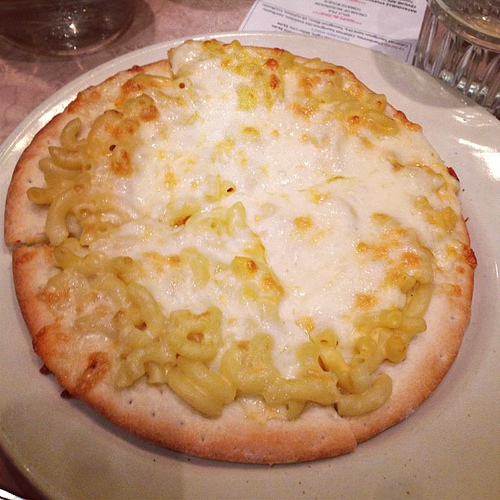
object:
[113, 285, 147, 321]
macaroni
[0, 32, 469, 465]
piece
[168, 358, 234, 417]
macaroni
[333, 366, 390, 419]
macaroni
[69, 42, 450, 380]
cheese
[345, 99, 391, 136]
macaroni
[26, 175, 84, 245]
macaroni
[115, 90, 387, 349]
melted cheese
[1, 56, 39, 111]
tablecloth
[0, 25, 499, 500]
plate